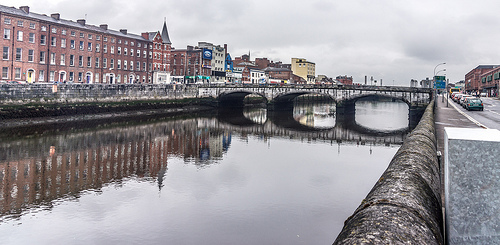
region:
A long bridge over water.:
[194, 77, 434, 126]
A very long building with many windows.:
[1, 4, 175, 101]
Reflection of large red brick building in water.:
[0, 114, 170, 224]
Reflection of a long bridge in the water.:
[197, 104, 412, 147]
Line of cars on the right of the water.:
[447, 91, 482, 112]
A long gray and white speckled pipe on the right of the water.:
[335, 89, 442, 244]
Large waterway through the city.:
[4, 99, 409, 241]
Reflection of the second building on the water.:
[167, 118, 232, 160]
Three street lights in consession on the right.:
[432, 64, 449, 85]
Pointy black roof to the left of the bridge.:
[159, 14, 172, 46]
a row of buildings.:
[0, 0, 317, 80]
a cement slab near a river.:
[421, 119, 498, 243]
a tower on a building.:
[157, 21, 182, 46]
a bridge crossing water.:
[208, 84, 435, 136]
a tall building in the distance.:
[282, 41, 331, 103]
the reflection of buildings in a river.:
[2, 81, 247, 231]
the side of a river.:
[0, 69, 201, 147]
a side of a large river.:
[328, 58, 458, 243]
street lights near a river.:
[413, 56, 456, 91]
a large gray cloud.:
[399, 23, 471, 91]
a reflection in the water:
[226, 127, 312, 144]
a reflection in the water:
[105, 151, 172, 193]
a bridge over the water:
[245, 74, 355, 129]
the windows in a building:
[115, 46, 147, 60]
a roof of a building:
[58, 11, 95, 31]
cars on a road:
[457, 86, 484, 111]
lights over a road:
[428, 57, 448, 87]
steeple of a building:
[158, 19, 171, 45]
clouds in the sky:
[310, 16, 365, 57]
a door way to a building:
[23, 66, 40, 86]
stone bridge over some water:
[196, 81, 433, 109]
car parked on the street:
[463, 97, 483, 111]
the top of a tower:
[158, 16, 171, 47]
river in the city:
[3, 100, 408, 244]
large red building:
[0, 0, 172, 92]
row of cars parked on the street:
[447, 85, 483, 111]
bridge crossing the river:
[195, 81, 437, 114]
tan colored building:
[287, 53, 317, 87]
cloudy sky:
[0, 0, 498, 85]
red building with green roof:
[460, 64, 499, 95]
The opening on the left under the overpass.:
[221, 86, 267, 123]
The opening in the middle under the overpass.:
[276, 91, 338, 124]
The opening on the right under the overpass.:
[346, 92, 407, 132]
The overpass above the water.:
[197, 72, 437, 97]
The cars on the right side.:
[448, 82, 482, 117]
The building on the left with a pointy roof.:
[150, 18, 175, 71]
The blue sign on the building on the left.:
[202, 45, 212, 58]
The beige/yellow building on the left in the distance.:
[292, 53, 317, 81]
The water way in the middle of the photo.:
[9, 77, 406, 243]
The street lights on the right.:
[425, 50, 452, 104]